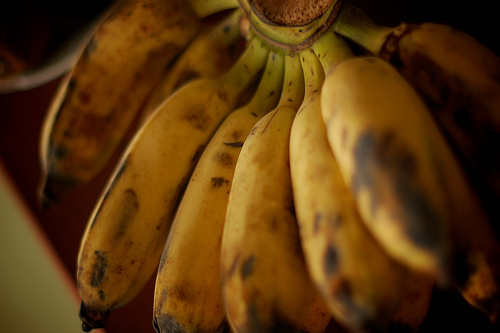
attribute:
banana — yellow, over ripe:
[239, 61, 288, 325]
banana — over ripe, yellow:
[320, 55, 480, 287]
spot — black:
[344, 117, 456, 269]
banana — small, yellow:
[75, 18, 266, 305]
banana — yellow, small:
[43, 6, 195, 187]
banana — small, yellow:
[222, 41, 323, 328]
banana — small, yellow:
[317, 30, 484, 297]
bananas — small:
[68, 57, 480, 315]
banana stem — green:
[258, 48, 285, 92]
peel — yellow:
[186, 228, 209, 290]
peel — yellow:
[241, 221, 286, 277]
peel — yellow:
[314, 196, 362, 254]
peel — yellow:
[319, 55, 400, 127]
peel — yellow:
[145, 123, 176, 175]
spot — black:
[303, 224, 357, 293]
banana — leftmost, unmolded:
[74, 34, 239, 331]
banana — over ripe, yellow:
[315, 57, 490, 304]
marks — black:
[300, 212, 369, 305]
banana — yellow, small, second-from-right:
[287, 46, 437, 325]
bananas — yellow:
[76, 22, 484, 332]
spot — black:
[351, 126, 438, 235]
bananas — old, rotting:
[40, 6, 497, 331]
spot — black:
[287, 131, 449, 247]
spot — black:
[304, 256, 375, 319]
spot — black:
[342, 135, 453, 252]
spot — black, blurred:
[327, 127, 438, 237]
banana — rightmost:
[333, 102, 449, 282]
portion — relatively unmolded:
[117, 137, 225, 267]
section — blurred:
[18, 17, 99, 226]